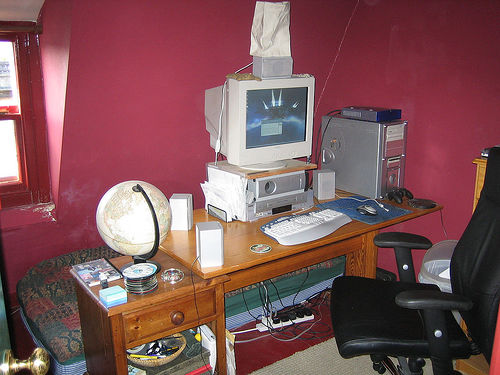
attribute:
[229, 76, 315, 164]
monitor — old, large, white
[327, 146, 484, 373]
office chair — black, swivel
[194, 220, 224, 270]
computer speaker — white, box shaped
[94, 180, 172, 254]
globe — white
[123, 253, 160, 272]
base — black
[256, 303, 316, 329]
power strip — completely filled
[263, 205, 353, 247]
keyboard — white and silver, white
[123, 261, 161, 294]
cds — stack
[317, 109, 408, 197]
computer tower — small, silver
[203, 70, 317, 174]
monitor — old, cathode ray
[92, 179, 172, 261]
world globe — white , round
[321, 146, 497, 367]
office chair — long backed, black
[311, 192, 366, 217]
mousepad — blue, large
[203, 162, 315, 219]
soundsystem — silver, white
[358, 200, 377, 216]
mouse — silver, black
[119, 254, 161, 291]
dvds — round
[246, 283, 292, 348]
cords — black, white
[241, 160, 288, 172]
base — round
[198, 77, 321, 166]
monitor — white, large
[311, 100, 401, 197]
computer — silver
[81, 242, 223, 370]
table — small, tan, wooden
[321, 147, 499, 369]
desk chair — black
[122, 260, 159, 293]
dvds — silver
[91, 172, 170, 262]
globe — round, white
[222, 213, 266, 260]
desk — wooden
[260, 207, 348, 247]
keyboard — white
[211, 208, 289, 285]
desk — brown, wooden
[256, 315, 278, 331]
outlet — white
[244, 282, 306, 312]
cords — black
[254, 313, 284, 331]
power strip — white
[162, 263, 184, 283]
ash tray — clear, glass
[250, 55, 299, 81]
computer speaker — light grey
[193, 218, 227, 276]
computer speaker — light grey